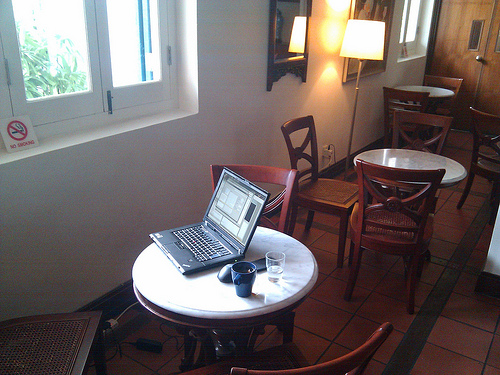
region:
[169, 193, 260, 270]
this is a laptop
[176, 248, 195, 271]
the laptop is black in color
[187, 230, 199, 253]
these are the buttons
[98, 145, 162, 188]
this is the wall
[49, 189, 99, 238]
the wall is white in color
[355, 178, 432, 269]
this is a chair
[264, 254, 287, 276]
this is a glass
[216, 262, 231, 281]
this is the mouse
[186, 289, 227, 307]
this is the table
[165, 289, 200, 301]
the table is white in color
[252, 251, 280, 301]
water glass on table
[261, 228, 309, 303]
water glass on table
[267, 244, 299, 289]
water glass on table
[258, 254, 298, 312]
water glass on table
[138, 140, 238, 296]
the laptop is open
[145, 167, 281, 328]
the laptop is open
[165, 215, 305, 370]
the laptop is open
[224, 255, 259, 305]
a blue cup on a table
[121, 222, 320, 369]
round table with white top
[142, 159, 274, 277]
a black laptop on a white table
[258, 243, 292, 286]
a glass of water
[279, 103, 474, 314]
two chairs in front a white table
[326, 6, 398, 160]
a lamp close to wall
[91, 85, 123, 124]
hinge of a window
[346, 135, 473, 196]
white top of a table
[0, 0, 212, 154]
window is white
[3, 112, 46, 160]
a no smoking sign on window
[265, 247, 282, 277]
water glass on table